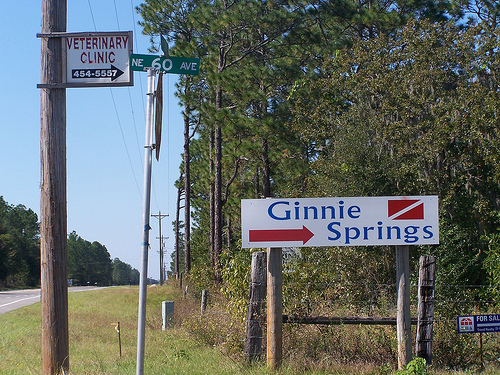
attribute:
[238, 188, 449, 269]
sign — white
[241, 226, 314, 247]
arrow — red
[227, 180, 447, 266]
white — sign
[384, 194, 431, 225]
block — red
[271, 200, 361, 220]
writing — blue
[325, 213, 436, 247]
writing — blue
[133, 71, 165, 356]
post — metal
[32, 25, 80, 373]
pole — wooden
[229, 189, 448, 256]
sign — white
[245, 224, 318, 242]
direction arrow — red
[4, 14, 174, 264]
sky — clear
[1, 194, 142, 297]
trees — tall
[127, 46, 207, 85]
street sign — green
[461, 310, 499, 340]
sale sign — blue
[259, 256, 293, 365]
pole — wooden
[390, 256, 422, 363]
pole — wooden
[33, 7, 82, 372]
pole — wooden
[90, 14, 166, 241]
wire — electrical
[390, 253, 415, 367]
pole — wooden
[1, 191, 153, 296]
trees — green